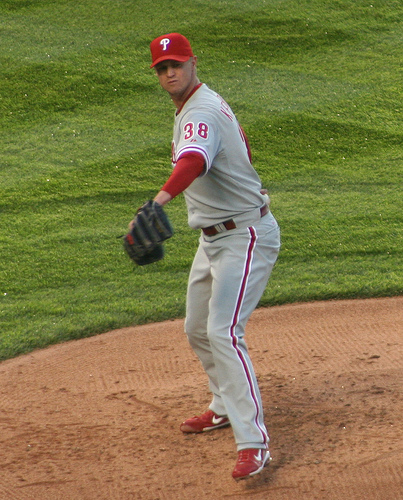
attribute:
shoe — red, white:
[226, 447, 282, 483]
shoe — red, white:
[176, 408, 233, 436]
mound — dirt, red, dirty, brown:
[7, 299, 402, 498]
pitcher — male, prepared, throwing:
[117, 31, 318, 487]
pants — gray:
[180, 228, 299, 450]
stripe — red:
[229, 226, 271, 452]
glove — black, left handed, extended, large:
[109, 200, 184, 268]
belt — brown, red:
[200, 202, 274, 238]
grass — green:
[3, 2, 402, 291]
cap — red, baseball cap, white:
[138, 28, 206, 66]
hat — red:
[148, 30, 193, 64]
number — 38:
[182, 118, 213, 146]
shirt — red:
[159, 152, 207, 205]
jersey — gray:
[171, 90, 267, 223]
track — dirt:
[248, 334, 385, 368]